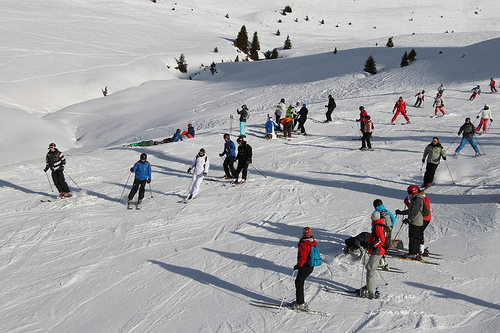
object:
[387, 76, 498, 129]
skiers snow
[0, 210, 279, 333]
snow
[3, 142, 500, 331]
ground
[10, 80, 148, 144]
valley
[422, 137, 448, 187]
person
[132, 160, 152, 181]
jacket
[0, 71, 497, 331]
slope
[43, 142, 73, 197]
person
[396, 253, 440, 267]
snowboarder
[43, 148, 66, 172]
snowsuit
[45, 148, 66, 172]
coat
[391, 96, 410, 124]
person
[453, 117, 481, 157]
person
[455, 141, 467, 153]
leg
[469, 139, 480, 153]
leg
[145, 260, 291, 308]
shadow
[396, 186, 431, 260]
skier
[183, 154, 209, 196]
white snowgear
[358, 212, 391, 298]
person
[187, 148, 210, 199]
person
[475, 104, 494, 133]
person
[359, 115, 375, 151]
person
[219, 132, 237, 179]
skier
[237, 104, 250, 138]
skier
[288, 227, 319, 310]
people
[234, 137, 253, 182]
skier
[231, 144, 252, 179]
snowgear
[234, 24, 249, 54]
tree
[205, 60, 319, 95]
snowy tundra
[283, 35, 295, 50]
trees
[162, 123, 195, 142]
couple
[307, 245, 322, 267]
backpack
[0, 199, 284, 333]
tracks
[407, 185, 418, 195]
helmet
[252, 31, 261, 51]
trees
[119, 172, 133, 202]
ski pole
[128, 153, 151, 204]
man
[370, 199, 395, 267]
skier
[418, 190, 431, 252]
skier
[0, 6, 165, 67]
snow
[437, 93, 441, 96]
hat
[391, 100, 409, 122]
ski suit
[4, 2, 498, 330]
ski slope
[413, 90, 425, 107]
skiers